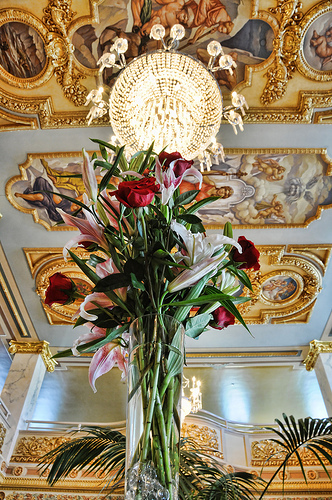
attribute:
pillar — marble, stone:
[0, 336, 58, 488]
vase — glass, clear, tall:
[127, 312, 187, 499]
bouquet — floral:
[37, 137, 258, 359]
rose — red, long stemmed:
[105, 173, 166, 213]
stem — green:
[135, 208, 158, 300]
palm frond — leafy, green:
[42, 421, 130, 482]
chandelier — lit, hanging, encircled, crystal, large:
[64, 27, 256, 181]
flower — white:
[159, 212, 243, 282]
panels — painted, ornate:
[3, 3, 326, 328]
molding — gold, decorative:
[10, 338, 57, 372]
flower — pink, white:
[46, 201, 111, 259]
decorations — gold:
[244, 8, 308, 119]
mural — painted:
[43, 163, 316, 232]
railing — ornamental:
[27, 417, 130, 428]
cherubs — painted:
[248, 157, 292, 224]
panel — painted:
[31, 158, 325, 224]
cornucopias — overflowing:
[40, 3, 93, 115]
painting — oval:
[3, 24, 48, 79]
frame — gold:
[27, 74, 52, 88]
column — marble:
[1, 352, 41, 475]